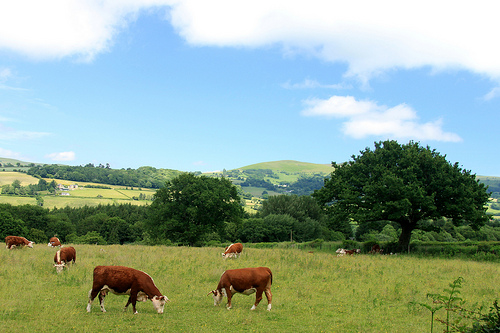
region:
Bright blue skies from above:
[117, 76, 265, 145]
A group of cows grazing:
[5, 236, 288, 316]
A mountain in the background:
[234, 154, 323, 188]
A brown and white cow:
[86, 264, 173, 326]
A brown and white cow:
[206, 265, 284, 310]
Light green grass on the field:
[311, 262, 423, 331]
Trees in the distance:
[114, 180, 227, 236]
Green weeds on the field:
[421, 278, 484, 330]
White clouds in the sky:
[295, 88, 429, 131]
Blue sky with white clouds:
[123, 62, 408, 136]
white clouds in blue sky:
[20, 15, 62, 53]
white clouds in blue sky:
[271, 24, 336, 94]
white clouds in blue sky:
[155, 34, 235, 88]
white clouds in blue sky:
[408, 40, 459, 101]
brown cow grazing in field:
[86, 252, 172, 317]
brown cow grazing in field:
[215, 260, 281, 306]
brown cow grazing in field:
[212, 230, 253, 261]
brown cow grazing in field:
[36, 245, 81, 276]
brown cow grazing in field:
[41, 232, 71, 247]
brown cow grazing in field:
[5, 231, 34, 258]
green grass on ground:
[386, 256, 407, 283]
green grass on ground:
[314, 263, 341, 291]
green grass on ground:
[294, 253, 314, 280]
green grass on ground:
[264, 238, 285, 254]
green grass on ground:
[181, 243, 202, 272]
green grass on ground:
[149, 251, 173, 273]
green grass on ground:
[21, 274, 57, 316]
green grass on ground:
[431, 250, 457, 285]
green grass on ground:
[365, 294, 393, 304]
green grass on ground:
[321, 282, 357, 311]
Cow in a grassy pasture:
[0, 222, 403, 323]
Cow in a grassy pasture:
[0, 231, 383, 317]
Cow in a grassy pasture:
[0, 228, 385, 324]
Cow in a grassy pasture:
[0, 221, 381, 321]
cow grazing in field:
[80, 262, 190, 328]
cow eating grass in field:
[74, 255, 177, 328]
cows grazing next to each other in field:
[76, 249, 291, 321]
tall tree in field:
[317, 123, 495, 267]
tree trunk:
[381, 222, 433, 264]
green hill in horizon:
[218, 153, 357, 190]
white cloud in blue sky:
[286, 82, 471, 160]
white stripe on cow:
[51, 249, 68, 261]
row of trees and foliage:
[7, 174, 324, 251]